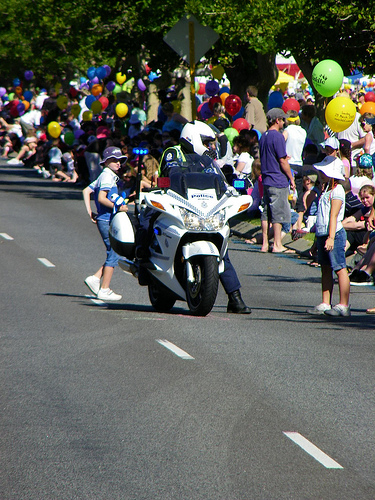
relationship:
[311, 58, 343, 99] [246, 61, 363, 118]
balloon in air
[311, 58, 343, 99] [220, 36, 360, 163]
balloon in air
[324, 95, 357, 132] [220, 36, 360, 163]
balloon in air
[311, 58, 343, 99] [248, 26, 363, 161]
balloon in air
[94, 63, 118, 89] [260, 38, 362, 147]
balloon in air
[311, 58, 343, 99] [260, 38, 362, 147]
balloon in air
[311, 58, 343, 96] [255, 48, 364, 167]
balloon in air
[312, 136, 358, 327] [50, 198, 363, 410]
child standing in street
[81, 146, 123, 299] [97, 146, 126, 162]
child wearing a dark hat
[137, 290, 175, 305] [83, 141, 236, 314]
tire on a motorcycle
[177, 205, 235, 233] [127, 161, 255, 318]
headlights on a motorcycle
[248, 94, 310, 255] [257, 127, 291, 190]
man wearing a purple shirt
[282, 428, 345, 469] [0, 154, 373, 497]
white line painted on road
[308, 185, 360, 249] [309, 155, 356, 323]
shirt on child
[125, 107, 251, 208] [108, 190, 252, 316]
man sitting on a bike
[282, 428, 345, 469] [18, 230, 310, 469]
white line on a street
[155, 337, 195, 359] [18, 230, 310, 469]
line on a street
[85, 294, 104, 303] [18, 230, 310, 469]
line on a street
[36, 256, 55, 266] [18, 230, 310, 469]
line on a street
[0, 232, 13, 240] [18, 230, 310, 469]
line on a street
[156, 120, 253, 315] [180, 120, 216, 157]
man wearing a helmet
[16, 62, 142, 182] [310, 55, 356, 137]
people holding balloons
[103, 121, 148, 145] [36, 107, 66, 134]
person holding balloon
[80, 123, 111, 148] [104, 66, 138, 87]
person holding balloon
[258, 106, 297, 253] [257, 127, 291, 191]
man wearing a purple shirt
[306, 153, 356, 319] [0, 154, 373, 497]
child standing on a road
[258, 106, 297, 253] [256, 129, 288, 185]
man wearing a shirt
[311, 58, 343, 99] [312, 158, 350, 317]
balloon above a girl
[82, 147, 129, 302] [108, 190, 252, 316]
child walking behind a bike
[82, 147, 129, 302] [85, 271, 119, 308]
child in white shoes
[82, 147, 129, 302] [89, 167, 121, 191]
child in a shirt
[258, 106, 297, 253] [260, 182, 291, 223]
man in shorts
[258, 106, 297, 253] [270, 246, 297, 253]
man in flip flop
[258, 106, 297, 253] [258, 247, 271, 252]
man in flip flop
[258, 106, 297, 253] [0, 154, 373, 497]
man standing on road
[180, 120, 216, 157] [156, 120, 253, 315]
helmet on a man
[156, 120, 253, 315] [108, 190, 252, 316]
man on a bike